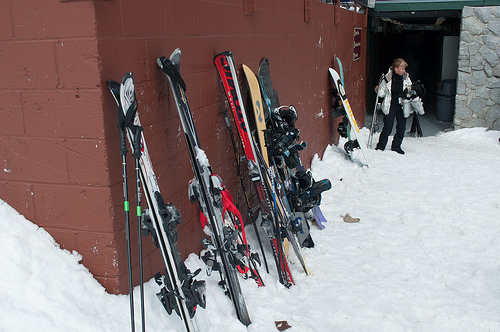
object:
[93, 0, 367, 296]
red wall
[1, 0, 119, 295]
red wall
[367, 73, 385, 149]
pole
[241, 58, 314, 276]
scattingboard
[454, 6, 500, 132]
wall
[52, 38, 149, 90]
brick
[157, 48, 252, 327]
ski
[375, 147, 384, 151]
shoe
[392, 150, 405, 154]
shoe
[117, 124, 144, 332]
pole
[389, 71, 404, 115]
shirt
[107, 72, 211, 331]
scatting board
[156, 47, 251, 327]
scatting board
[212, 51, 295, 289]
scatting board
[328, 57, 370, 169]
scatting board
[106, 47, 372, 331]
skiis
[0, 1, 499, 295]
building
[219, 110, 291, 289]
pole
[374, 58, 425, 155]
person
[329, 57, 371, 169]
skis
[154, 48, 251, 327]
skis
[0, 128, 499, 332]
snow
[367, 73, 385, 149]
skis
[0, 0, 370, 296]
wall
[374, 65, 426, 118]
coat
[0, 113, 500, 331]
ground